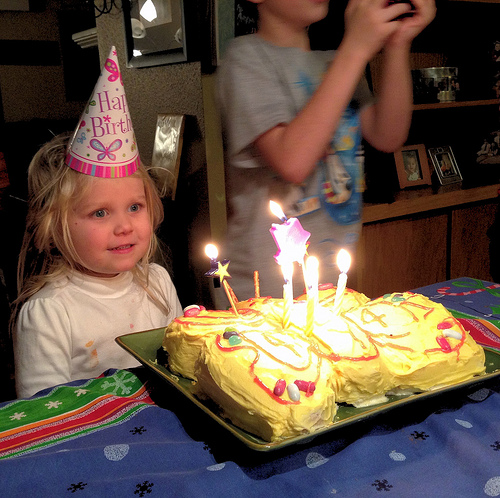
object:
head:
[27, 132, 154, 276]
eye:
[88, 204, 112, 220]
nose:
[111, 206, 134, 239]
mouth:
[104, 239, 138, 258]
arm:
[12, 296, 74, 401]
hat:
[63, 43, 145, 183]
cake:
[159, 279, 489, 445]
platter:
[113, 323, 500, 454]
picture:
[399, 146, 424, 184]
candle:
[331, 246, 354, 315]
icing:
[421, 315, 467, 364]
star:
[203, 256, 234, 290]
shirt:
[11, 260, 190, 404]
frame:
[427, 142, 464, 187]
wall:
[89, 0, 231, 314]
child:
[6, 132, 186, 402]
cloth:
[0, 275, 499, 496]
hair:
[6, 126, 181, 336]